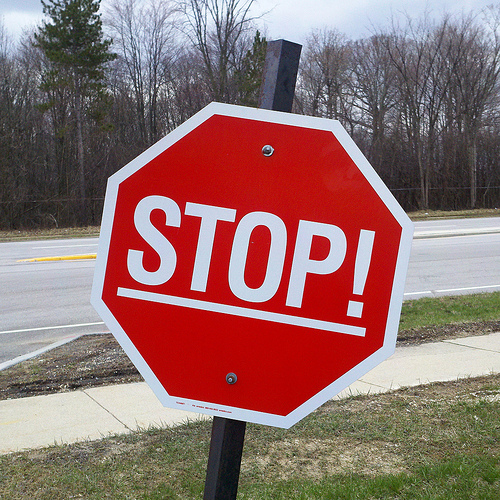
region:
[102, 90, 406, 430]
Red stop sign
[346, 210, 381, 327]
White exclamation mark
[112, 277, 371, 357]
Underline under words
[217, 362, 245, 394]
Small gray pin in sign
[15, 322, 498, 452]
sidewalk in background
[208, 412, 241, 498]
Black part of sign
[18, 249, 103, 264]
Yellow line in background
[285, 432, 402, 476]
Sandy patch in grass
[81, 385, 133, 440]
Groove in sidewalk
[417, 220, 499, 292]
Street is gray and faded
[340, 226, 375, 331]
exclamation point on sign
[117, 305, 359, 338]
white line on stop sign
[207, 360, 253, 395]
a screw on sign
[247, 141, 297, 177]
another screw on stop sign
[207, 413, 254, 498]
pole that is holding sign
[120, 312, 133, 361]
white border on sign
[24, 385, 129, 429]
part of the sidewalk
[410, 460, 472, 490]
a patch of green grass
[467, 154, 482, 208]
trunk on the tree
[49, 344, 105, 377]
dirt patch near street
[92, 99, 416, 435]
Red stop sign trimmed in white.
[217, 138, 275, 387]
Screws used to hold stop sign on post.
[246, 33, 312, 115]
Top of gray rusted post holding stop sign.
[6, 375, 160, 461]
Concrete sidewalk near road.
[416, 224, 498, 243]
Median strip to separate roads.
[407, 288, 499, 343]
Grass easement next to sidewalk.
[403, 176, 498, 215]
Fence running along side of road.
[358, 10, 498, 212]
Bare trees on other side of fence.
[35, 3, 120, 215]
Evergreen pine tree on other side of fence.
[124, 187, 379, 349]
Stop written in white on stop sign.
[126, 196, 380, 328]
Red sign has white lettering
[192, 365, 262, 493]
Sign is screwed to pole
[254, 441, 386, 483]
Dead patch of grass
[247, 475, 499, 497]
Grass is green and cut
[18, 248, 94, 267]
Yellow median in street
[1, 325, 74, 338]
White line on street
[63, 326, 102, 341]
Curb has a point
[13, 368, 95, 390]
Dirt is brown and wet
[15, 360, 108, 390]
Tire track in mud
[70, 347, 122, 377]
White rocks in the mud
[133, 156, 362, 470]
a stop sign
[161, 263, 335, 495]
a stop sign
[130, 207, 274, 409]
a stop sign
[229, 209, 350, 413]
a stop sign